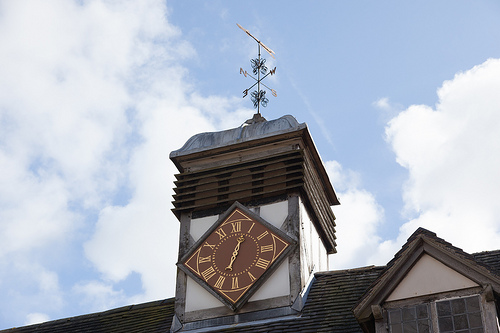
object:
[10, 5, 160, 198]
cloud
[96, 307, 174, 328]
shingles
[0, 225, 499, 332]
roof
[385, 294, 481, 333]
window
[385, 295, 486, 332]
panes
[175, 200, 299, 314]
green trays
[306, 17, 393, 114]
sky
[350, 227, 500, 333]
home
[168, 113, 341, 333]
chimney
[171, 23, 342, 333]
clock tower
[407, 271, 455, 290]
wall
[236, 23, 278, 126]
compass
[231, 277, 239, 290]
numerals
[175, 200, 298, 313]
clock